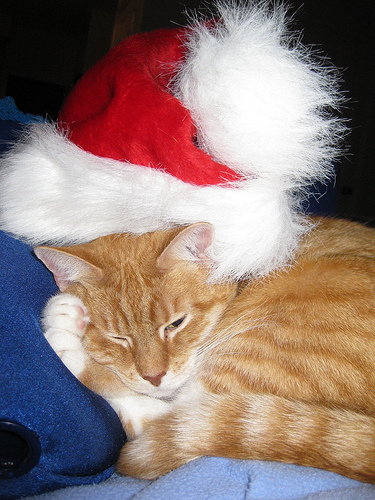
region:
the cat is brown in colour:
[53, 223, 309, 431]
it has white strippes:
[234, 294, 366, 413]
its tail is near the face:
[122, 376, 335, 498]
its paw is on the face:
[12, 268, 195, 394]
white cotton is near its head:
[8, 6, 349, 273]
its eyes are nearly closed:
[85, 300, 226, 355]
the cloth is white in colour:
[137, 465, 234, 497]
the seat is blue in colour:
[2, 292, 106, 489]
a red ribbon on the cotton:
[66, 37, 251, 197]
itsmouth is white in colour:
[121, 358, 214, 416]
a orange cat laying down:
[46, 231, 372, 498]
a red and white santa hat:
[34, 41, 295, 215]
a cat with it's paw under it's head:
[40, 275, 200, 380]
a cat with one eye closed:
[100, 311, 206, 357]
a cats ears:
[32, 217, 230, 289]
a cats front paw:
[42, 294, 89, 332]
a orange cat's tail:
[105, 394, 360, 489]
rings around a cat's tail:
[142, 422, 355, 480]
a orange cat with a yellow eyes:
[151, 302, 197, 353]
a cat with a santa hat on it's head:
[32, 153, 274, 330]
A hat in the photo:
[148, 78, 254, 146]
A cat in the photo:
[116, 268, 324, 403]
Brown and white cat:
[229, 330, 351, 403]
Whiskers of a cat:
[188, 307, 288, 352]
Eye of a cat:
[162, 314, 189, 339]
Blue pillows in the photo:
[42, 393, 96, 469]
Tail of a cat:
[130, 408, 228, 468]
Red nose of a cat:
[144, 374, 165, 386]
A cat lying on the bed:
[67, 222, 360, 489]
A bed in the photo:
[12, 333, 286, 496]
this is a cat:
[121, 263, 354, 466]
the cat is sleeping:
[119, 249, 361, 457]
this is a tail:
[122, 399, 325, 483]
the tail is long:
[114, 393, 333, 473]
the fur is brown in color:
[267, 258, 355, 370]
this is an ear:
[159, 221, 208, 266]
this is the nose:
[147, 369, 163, 382]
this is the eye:
[159, 314, 188, 338]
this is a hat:
[104, 83, 177, 146]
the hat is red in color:
[116, 101, 163, 149]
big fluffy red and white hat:
[35, 25, 281, 258]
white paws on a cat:
[43, 292, 91, 368]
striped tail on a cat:
[142, 385, 364, 486]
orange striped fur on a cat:
[233, 310, 366, 411]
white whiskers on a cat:
[188, 291, 274, 363]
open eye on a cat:
[153, 308, 198, 340]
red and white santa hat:
[10, 7, 319, 272]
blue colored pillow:
[24, 393, 100, 473]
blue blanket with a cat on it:
[125, 472, 216, 499]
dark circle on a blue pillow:
[2, 415, 42, 485]